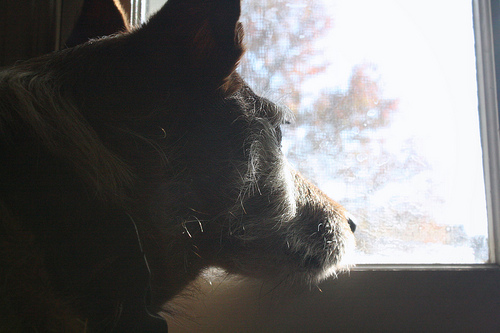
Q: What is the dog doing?
A: Looking out the window.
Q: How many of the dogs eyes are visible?
A: One.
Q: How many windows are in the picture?
A: One.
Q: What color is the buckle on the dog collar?
A: Black.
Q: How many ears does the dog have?
A: Two.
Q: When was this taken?
A: Daytime.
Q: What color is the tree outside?
A: Red.